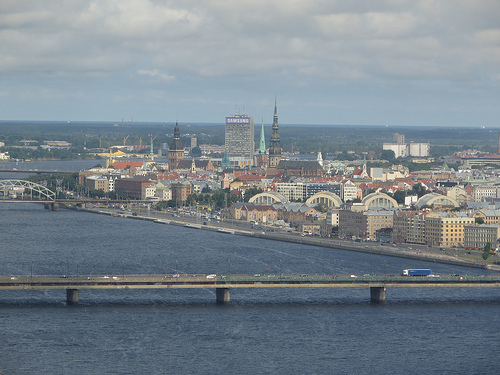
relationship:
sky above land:
[1, 2, 500, 128] [3, 120, 500, 271]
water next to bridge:
[1, 203, 500, 374] [1, 272, 500, 307]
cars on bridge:
[11, 272, 496, 280] [1, 272, 500, 307]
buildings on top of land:
[75, 95, 500, 255] [3, 120, 500, 271]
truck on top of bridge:
[402, 268, 432, 277] [1, 272, 500, 307]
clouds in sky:
[1, 1, 500, 98] [1, 2, 500, 128]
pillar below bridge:
[65, 287, 80, 305] [1, 272, 500, 307]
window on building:
[446, 219, 450, 225] [424, 207, 477, 248]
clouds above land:
[1, 1, 500, 98] [3, 120, 500, 271]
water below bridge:
[1, 203, 500, 374] [1, 272, 500, 307]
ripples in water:
[43, 338, 140, 353] [1, 203, 500, 374]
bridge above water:
[1, 272, 500, 307] [1, 203, 500, 374]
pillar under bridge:
[217, 284, 232, 307] [1, 272, 500, 307]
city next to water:
[35, 94, 500, 256] [1, 203, 500, 374]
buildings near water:
[75, 95, 500, 255] [1, 203, 500, 374]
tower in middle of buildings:
[267, 101, 282, 173] [75, 95, 500, 255]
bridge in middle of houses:
[3, 176, 171, 218] [77, 171, 222, 213]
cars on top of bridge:
[11, 272, 496, 280] [1, 272, 500, 307]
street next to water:
[67, 195, 500, 270] [1, 203, 500, 374]